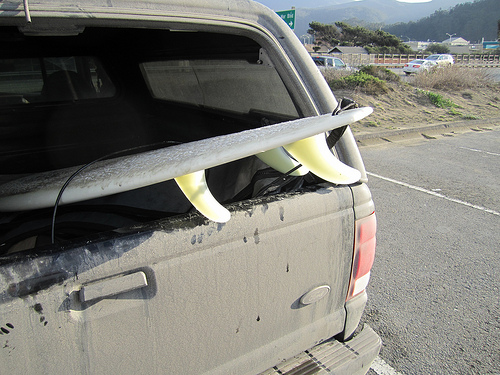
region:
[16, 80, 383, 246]
white surfboard in back of SUV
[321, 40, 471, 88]
cars on street in background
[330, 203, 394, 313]
rear brake lights on SUV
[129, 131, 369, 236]
three fins on surfboard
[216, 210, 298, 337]
dust and dirt covering SUV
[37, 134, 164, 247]
black surfboard cord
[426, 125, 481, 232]
white lines in parking lot to mark parking spots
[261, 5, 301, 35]
green and white street sign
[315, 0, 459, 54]
hills and mountains in the background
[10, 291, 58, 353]
clean spots on dirty SUV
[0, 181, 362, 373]
a dusty tail gate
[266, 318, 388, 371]
a dusty back bumper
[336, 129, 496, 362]
a paved parking lot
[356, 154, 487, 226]
a white stripe in a parking lot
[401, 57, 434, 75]
a car driving on a road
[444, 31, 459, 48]
a double headed light pole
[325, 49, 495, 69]
a fence alongside a road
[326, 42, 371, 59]
a house behind a fence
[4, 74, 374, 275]
a board in a truck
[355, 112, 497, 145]
a curb at a parking lot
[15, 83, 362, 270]
surfboard hanging out of car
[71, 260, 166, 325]
handle of the car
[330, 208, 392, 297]
red light on back of car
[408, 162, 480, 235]
white line on road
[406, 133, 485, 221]
empty parking space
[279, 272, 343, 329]
brand of the car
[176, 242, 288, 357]
dirt on the back of car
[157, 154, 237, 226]
bottom part of the surfboard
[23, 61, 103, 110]
front seat of car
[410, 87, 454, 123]
grass and dirt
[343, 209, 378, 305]
red and white tail light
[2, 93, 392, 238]
white surf board with yellow fins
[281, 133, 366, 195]
yellow surfboard fin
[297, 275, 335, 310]
dust covered ford logo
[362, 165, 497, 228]
white parking lot paint line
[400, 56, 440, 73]
white car with red tail lights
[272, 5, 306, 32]
corner of a green and white traffic sign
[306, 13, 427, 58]
wide evergreen shrub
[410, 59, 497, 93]
tan grass shrub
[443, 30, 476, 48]
white house with dark roof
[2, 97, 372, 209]
grey surfboard in the back of truck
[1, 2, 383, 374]
dirty Ford SUV parked in stall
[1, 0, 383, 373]
Ford truck with surfboard in the back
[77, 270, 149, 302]
latch to open gate on SUV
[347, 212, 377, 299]
white and red brake lights on right rear of Ford truck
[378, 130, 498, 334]
parking lot stalls for automobiles to park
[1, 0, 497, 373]
parking lot stalls for visitors at the beach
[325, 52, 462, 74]
vehicles traveling on the street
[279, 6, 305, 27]
corner of street sign to exit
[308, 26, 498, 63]
residential area behind the fence, across the fence